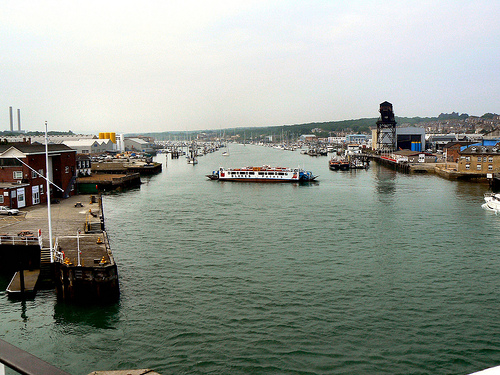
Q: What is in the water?
A: Boats.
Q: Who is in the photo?
A: Nobody.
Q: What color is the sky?
A: Gray.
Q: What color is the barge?
A: White.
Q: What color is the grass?
A: Green.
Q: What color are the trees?
A: Green.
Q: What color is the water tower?
A: Black.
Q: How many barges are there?
A: One.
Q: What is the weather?
A: Cloudy.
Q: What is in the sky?
A: Clouds.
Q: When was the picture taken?
A: Daytime.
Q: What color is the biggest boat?
A: Red, white and blue.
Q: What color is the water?
A: Green.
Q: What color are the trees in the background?
A: Green.